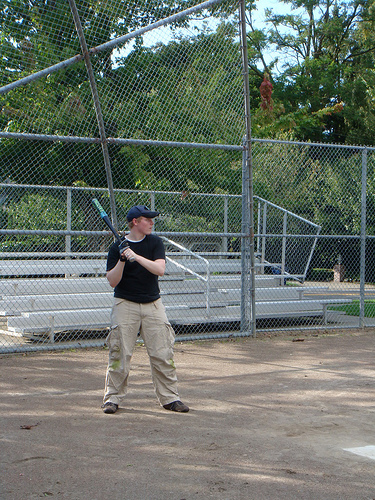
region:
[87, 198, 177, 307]
the man is carrying a bat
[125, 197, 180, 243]
the man is wearing a hat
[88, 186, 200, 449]
the man is wearing clothes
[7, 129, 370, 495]
the man is alone in the photo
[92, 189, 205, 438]
the man is standing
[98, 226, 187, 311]
the man is wearing a black shirt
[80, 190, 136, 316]
the bat is black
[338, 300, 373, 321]
the grass is green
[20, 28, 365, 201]
the trees are green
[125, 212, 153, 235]
the man has brown hair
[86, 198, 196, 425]
The guy is playing baseball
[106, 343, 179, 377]
The baseball player has green grass stains on his pants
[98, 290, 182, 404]
The baseball player is wearing khaki pants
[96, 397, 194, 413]
The baseball player is wearing brown shoes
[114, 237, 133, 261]
He has a batting glove on one hand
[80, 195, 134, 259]
The baseball bat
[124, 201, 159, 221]
He is wearing a navy baseball cap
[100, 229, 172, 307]
The baseball player is wearing a black shirt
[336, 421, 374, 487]
Home plate on the baseball field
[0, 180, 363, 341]
The bleachers at the baseball field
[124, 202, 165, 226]
cap is blue in color.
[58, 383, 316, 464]
shadow falls on ground.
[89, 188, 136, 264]
man is holding the baseball bat.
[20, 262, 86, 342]
steps are white in color.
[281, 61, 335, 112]
trees are green in color.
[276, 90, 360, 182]
trees are behind the fence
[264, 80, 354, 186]
fence is blue in color.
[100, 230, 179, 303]
boy is wearing black shirt.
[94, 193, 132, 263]
bat is black in color.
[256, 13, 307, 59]
sky is blue in color.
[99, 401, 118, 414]
Man's right shoe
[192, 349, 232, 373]
Portion of the ground not covered with shadows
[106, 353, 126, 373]
Grass stain on the man's right knee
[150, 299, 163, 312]
Left pocket on the man's pants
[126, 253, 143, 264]
Round base of the bat handle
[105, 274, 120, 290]
Man's right elbow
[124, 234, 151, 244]
White collar on the man's black shirt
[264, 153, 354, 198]
Section of the chain link fence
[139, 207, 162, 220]
Brim of the cap on the man's head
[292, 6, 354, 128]
Trees in the background above the fence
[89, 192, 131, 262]
Baseball bat ready strike.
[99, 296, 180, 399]
Cargo pants provide pockets.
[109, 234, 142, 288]
Only one glove worn.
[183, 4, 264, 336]
High fence protects fans.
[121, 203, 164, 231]
Wearing blue baseball cap.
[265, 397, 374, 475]
Home plate shown right.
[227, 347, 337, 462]
Baseball field shows shadows.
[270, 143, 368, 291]
Trees green foliage here.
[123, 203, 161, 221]
a blue baseball cap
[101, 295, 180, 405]
a boy's brown pants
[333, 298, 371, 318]
a section of green grass